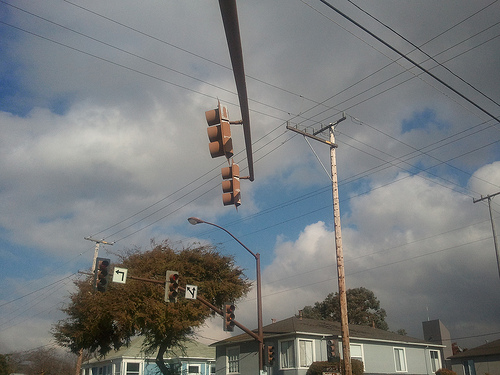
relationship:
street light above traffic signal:
[186, 215, 267, 374] [164, 268, 181, 303]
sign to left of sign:
[111, 266, 128, 283] [182, 284, 199, 298]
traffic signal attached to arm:
[164, 268, 181, 303] [77, 270, 258, 347]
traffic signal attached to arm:
[92, 257, 113, 283] [77, 270, 258, 347]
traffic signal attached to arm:
[222, 303, 237, 325] [77, 270, 258, 347]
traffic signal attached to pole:
[263, 344, 276, 367] [256, 252, 266, 374]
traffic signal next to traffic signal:
[204, 99, 234, 157] [222, 159, 244, 207]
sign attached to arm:
[111, 266, 128, 283] [77, 270, 258, 347]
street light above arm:
[186, 215, 267, 374] [77, 270, 258, 347]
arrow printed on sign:
[115, 270, 126, 281] [111, 266, 128, 283]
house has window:
[207, 316, 448, 374] [393, 348, 408, 372]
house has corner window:
[207, 316, 448, 374] [277, 338, 315, 365]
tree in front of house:
[49, 240, 256, 374] [80, 324, 219, 374]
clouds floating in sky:
[191, 162, 499, 349] [0, 1, 498, 351]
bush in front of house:
[307, 359, 364, 374] [207, 316, 448, 374]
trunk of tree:
[155, 343, 175, 374] [49, 240, 256, 374]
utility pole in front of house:
[285, 115, 352, 373] [207, 316, 448, 374]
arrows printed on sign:
[185, 286, 197, 297] [182, 284, 199, 298]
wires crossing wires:
[1, 2, 499, 210] [2, 2, 499, 330]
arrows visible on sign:
[185, 286, 197, 297] [182, 284, 199, 298]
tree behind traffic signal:
[49, 240, 256, 374] [164, 268, 181, 303]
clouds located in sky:
[191, 162, 499, 349] [0, 1, 498, 351]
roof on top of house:
[210, 316, 464, 341] [207, 316, 448, 374]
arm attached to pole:
[77, 270, 258, 347] [256, 252, 266, 374]